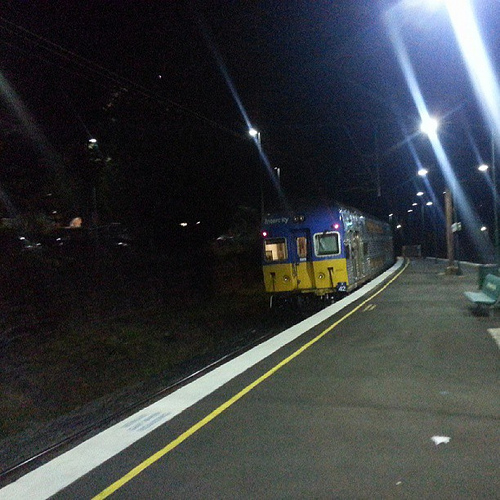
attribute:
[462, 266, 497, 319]
bench — green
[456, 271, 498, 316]
bench — green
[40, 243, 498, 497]
floor — black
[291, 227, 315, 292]
door — narrow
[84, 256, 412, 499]
stripe — yellow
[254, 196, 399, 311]
train — blue, yellow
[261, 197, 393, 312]
train — yellow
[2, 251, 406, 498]
stripe — white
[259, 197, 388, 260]
area — blue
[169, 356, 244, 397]
line — white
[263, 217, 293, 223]
writing — white